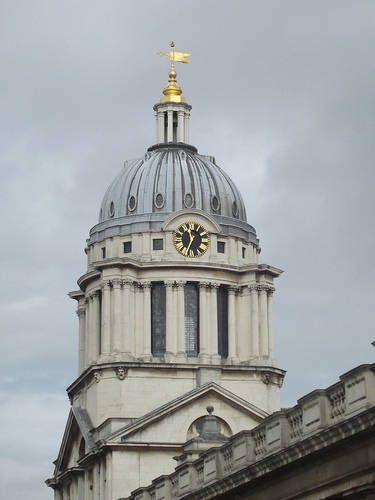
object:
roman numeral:
[182, 224, 188, 230]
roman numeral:
[173, 236, 182, 240]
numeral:
[188, 221, 195, 230]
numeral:
[199, 229, 206, 236]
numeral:
[201, 237, 209, 242]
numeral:
[182, 245, 189, 256]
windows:
[151, 281, 167, 358]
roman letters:
[176, 227, 183, 235]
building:
[42, 40, 373, 497]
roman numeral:
[197, 224, 202, 231]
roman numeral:
[199, 242, 207, 251]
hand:
[188, 227, 194, 240]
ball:
[206, 404, 214, 412]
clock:
[173, 221, 211, 258]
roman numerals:
[197, 248, 202, 256]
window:
[183, 279, 198, 356]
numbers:
[176, 241, 185, 249]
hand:
[187, 235, 196, 251]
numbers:
[190, 248, 194, 256]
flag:
[157, 40, 191, 69]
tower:
[44, 39, 287, 500]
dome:
[84, 142, 261, 251]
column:
[143, 292, 151, 356]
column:
[165, 289, 174, 352]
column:
[177, 290, 185, 353]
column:
[199, 290, 207, 354]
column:
[211, 291, 219, 355]